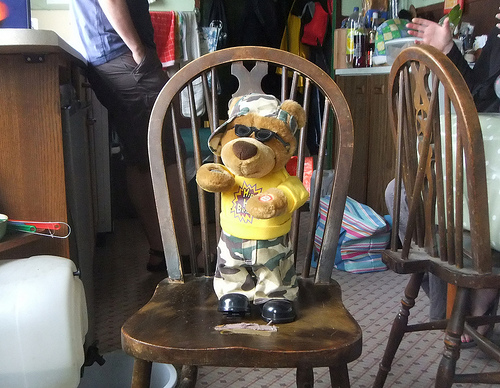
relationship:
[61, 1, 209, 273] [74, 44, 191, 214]
person wearing shorts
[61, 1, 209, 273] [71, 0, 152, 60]
person wearing shirt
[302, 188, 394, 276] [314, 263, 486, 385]
striped bag on floor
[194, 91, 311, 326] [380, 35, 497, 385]
bear standing on a chair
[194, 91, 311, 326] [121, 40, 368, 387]
bear on chair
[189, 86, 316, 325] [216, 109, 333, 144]
bear wearing toy sunglasses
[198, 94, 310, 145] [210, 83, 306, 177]
hat on head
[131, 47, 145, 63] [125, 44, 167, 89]
hand in pocket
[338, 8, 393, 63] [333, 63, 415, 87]
bottles on counter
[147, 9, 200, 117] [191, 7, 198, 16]
towels on holder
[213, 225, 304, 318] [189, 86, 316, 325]
pants on bear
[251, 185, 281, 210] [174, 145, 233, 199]
red button on hand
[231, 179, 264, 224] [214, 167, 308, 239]
logo on shirt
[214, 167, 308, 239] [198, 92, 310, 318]
shirt on teddybear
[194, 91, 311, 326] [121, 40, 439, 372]
bear on chair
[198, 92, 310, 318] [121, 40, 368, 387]
teddybear on chair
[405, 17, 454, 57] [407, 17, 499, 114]
hand on person